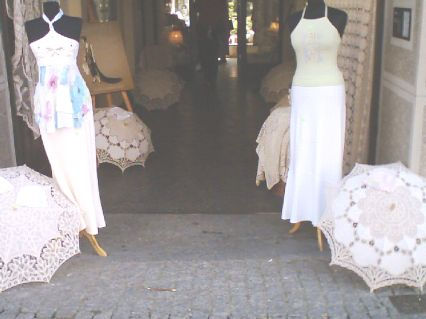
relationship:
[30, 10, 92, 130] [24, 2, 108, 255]
tank on dummy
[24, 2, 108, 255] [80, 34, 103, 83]
dummy of woman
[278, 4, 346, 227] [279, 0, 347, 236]
dress on dummy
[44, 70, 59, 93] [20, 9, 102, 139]
design on dress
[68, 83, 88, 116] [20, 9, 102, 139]
design on dress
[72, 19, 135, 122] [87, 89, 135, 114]
easel on wooden structure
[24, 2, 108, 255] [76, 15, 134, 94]
dummy shown on painting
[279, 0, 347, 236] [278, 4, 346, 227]
dummy wearing dress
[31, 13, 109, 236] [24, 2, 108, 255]
dress on dummy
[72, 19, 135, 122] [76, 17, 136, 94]
easel holding portrait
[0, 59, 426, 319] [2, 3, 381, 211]
sidewalk leading up to store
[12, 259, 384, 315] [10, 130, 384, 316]
cobblestones in ground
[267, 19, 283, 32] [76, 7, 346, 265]
light inside building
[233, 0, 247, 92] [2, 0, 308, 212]
pillar on room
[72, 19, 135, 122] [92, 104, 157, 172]
easel near umbrella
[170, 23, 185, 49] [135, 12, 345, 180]
light in building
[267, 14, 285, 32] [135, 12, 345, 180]
light in building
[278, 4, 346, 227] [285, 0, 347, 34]
dress on dummy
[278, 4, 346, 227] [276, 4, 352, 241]
dress on mannequin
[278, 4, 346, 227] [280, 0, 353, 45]
dress on mannequin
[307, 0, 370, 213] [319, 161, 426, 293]
wall near umbrella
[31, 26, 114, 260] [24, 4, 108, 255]
dress on a dummy